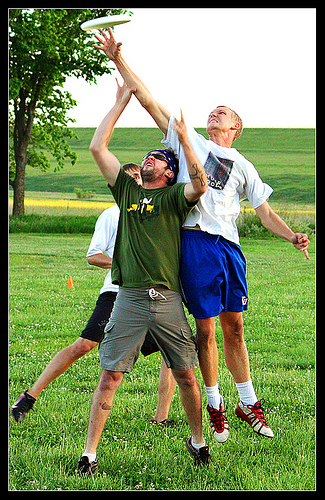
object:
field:
[9, 126, 317, 492]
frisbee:
[80, 15, 132, 31]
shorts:
[79, 291, 160, 357]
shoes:
[206, 398, 274, 443]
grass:
[7, 127, 317, 489]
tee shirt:
[161, 115, 273, 246]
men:
[10, 25, 311, 480]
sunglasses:
[141, 153, 169, 168]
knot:
[149, 288, 158, 300]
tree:
[8, 8, 133, 217]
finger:
[304, 250, 310, 260]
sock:
[235, 378, 258, 406]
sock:
[204, 384, 220, 411]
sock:
[191, 435, 205, 452]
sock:
[82, 449, 96, 463]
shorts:
[178, 227, 249, 320]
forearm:
[182, 142, 208, 202]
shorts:
[97, 285, 197, 371]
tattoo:
[189, 163, 205, 186]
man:
[74, 78, 216, 480]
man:
[92, 27, 310, 444]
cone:
[67, 276, 75, 289]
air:
[4, 9, 318, 130]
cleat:
[206, 396, 229, 443]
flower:
[33, 200, 101, 205]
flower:
[44, 199, 111, 208]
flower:
[50, 202, 106, 206]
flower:
[47, 202, 116, 207]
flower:
[8, 197, 116, 209]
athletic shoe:
[206, 394, 230, 443]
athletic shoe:
[234, 398, 274, 438]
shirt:
[86, 200, 121, 294]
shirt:
[107, 166, 199, 293]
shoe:
[73, 456, 98, 480]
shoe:
[185, 435, 216, 471]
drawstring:
[149, 288, 167, 300]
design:
[203, 151, 234, 190]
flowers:
[135, 482, 154, 490]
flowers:
[273, 403, 315, 426]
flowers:
[18, 348, 35, 364]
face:
[140, 151, 168, 182]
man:
[9, 163, 177, 428]